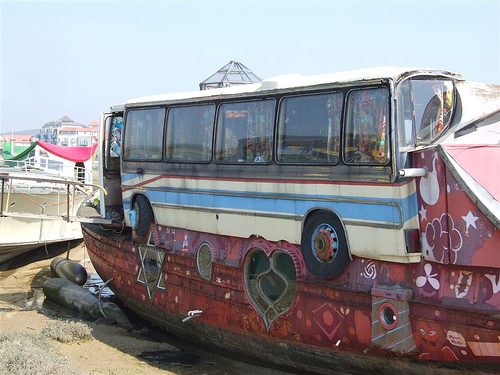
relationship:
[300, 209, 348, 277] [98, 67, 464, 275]
wheel on bus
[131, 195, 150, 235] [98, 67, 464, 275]
wheel on bus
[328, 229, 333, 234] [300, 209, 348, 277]
hole in wheel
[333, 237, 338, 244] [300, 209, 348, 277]
hole in wheel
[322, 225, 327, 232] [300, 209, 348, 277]
hole in wheel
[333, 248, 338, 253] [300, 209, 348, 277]
hole in wheel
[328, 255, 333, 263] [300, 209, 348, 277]
hole in wheel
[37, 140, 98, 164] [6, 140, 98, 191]
roof on building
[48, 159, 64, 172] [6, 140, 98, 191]
window on building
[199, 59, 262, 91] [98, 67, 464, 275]
dome behind bus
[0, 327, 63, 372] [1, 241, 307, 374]
bush on ground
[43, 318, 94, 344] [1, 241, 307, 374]
bush on ground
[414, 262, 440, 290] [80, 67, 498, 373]
clover on boat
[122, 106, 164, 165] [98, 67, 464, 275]
window on bus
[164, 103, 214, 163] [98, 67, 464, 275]
window on bus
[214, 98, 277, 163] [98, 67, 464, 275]
window on bus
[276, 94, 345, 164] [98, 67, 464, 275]
window on bus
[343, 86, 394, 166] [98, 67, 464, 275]
window on bus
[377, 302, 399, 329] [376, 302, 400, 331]
edge of edge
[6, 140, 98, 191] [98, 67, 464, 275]
building behind bus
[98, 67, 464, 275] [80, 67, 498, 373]
bus on boat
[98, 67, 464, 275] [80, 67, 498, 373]
bus morphed with boat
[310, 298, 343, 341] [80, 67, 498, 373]
design on boat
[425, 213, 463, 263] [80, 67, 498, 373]
design on boat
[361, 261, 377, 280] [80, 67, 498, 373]
design on boat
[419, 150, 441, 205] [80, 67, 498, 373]
design on boat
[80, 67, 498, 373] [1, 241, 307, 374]
boat on ground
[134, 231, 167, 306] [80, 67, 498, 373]
star of david on boat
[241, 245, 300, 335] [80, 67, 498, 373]
heart on boat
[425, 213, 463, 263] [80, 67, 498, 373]
cloud on boat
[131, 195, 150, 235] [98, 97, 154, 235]
wheel on front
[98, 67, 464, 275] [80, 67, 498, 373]
bus on top of boat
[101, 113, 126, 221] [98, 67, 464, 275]
door on bus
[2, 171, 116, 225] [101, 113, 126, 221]
walkway to door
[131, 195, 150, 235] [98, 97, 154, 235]
wheel in front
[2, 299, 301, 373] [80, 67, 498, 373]
sand under boat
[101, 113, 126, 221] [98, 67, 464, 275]
door of bus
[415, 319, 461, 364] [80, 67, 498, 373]
character on boat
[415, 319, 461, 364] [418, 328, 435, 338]
character has eyes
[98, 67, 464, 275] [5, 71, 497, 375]
bus in photo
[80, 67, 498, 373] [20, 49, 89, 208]
boat in photo